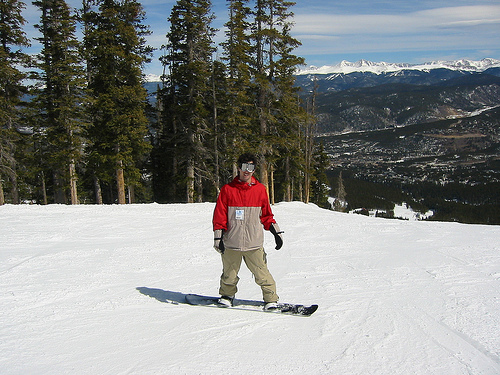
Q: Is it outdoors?
A: Yes, it is outdoors.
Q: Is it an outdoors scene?
A: Yes, it is outdoors.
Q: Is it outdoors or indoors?
A: It is outdoors.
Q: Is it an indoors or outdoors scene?
A: It is outdoors.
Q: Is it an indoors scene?
A: No, it is outdoors.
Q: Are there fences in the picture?
A: No, there are no fences.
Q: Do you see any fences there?
A: No, there are no fences.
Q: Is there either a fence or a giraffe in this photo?
A: No, there are no fences or giraffes.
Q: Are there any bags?
A: No, there are no bags.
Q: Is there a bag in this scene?
A: No, there are no bags.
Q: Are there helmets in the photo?
A: No, there are no helmets.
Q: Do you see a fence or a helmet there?
A: No, there are no helmets or fences.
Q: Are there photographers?
A: No, there are no photographers.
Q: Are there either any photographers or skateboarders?
A: No, there are no photographers or skateboarders.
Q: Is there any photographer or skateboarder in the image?
A: No, there are no photographers or skateboarders.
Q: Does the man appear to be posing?
A: Yes, the man is posing.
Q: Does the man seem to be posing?
A: Yes, the man is posing.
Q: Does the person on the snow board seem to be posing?
A: Yes, the man is posing.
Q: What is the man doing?
A: The man is posing.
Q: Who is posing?
A: The man is posing.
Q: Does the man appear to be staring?
A: No, the man is posing.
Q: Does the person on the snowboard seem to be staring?
A: No, the man is posing.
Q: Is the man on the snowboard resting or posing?
A: The man is posing.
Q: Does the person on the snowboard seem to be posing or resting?
A: The man is posing.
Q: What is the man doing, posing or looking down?
A: The man is posing.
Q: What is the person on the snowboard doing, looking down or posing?
A: The man is posing.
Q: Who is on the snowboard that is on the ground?
A: The man is on the snowboard.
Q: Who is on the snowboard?
A: The man is on the snowboard.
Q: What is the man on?
A: The man is on the snowboard.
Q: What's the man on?
A: The man is on the snowboard.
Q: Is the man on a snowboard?
A: Yes, the man is on a snowboard.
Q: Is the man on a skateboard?
A: No, the man is on a snowboard.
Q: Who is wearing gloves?
A: The man is wearing gloves.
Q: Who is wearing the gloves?
A: The man is wearing gloves.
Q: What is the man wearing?
A: The man is wearing gloves.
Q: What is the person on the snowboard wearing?
A: The man is wearing gloves.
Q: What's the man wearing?
A: The man is wearing gloves.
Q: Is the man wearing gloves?
A: Yes, the man is wearing gloves.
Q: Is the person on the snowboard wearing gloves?
A: Yes, the man is wearing gloves.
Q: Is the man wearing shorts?
A: No, the man is wearing gloves.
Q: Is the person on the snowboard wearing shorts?
A: No, the man is wearing gloves.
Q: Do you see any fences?
A: No, there are no fences.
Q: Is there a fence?
A: No, there are no fences.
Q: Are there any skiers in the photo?
A: No, there are no skiers.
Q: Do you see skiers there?
A: No, there are no skiers.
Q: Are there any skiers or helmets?
A: No, there are no skiers or helmets.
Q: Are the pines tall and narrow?
A: Yes, the pines are tall and narrow.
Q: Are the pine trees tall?
A: Yes, the pine trees are tall.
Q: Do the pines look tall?
A: Yes, the pines are tall.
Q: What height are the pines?
A: The pines are tall.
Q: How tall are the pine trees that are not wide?
A: The pine trees are tall.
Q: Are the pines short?
A: No, the pines are tall.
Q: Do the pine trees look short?
A: No, the pine trees are tall.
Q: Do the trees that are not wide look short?
A: No, the pine trees are tall.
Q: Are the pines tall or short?
A: The pines are tall.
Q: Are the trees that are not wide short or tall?
A: The pines are tall.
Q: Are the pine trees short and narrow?
A: No, the pine trees are narrow but tall.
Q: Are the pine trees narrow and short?
A: No, the pine trees are narrow but tall.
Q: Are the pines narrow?
A: Yes, the pines are narrow.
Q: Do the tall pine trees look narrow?
A: Yes, the pine trees are narrow.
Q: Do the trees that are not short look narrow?
A: Yes, the pine trees are narrow.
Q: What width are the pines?
A: The pines are narrow.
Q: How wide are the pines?
A: The pines are narrow.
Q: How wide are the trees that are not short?
A: The pines are narrow.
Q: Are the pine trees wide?
A: No, the pine trees are narrow.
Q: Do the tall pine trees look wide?
A: No, the pine trees are narrow.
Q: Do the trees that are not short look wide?
A: No, the pine trees are narrow.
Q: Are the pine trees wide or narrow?
A: The pine trees are narrow.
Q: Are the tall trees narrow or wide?
A: The pine trees are narrow.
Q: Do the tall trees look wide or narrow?
A: The pine trees are narrow.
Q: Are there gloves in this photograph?
A: Yes, there are gloves.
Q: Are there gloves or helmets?
A: Yes, there are gloves.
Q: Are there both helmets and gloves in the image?
A: No, there are gloves but no helmets.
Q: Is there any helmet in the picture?
A: No, there are no helmets.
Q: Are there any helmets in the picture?
A: No, there are no helmets.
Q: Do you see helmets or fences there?
A: No, there are no helmets or fences.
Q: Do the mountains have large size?
A: Yes, the mountains are large.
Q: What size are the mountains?
A: The mountains are large.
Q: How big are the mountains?
A: The mountains are large.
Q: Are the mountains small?
A: No, the mountains are large.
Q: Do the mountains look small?
A: No, the mountains are large.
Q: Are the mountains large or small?
A: The mountains are large.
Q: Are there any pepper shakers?
A: No, there are no pepper shakers.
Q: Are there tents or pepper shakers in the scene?
A: No, there are no pepper shakers or tents.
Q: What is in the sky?
A: The clouds are in the sky.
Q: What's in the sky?
A: The clouds are in the sky.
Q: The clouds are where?
A: The clouds are in the sky.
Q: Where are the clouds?
A: The clouds are in the sky.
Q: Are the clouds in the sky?
A: Yes, the clouds are in the sky.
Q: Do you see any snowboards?
A: Yes, there is a snowboard.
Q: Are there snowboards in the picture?
A: Yes, there is a snowboard.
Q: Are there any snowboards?
A: Yes, there is a snowboard.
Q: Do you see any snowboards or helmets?
A: Yes, there is a snowboard.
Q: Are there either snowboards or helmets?
A: Yes, there is a snowboard.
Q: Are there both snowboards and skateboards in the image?
A: No, there is a snowboard but no skateboards.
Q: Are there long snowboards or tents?
A: Yes, there is a long snowboard.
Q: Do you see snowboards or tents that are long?
A: Yes, the snowboard is long.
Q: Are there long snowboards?
A: Yes, there is a long snowboard.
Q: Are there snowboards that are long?
A: Yes, there is a snowboard that is long.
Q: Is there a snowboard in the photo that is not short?
A: Yes, there is a long snowboard.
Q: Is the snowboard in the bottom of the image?
A: Yes, the snowboard is in the bottom of the image.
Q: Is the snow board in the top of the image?
A: No, the snow board is in the bottom of the image.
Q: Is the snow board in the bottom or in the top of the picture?
A: The snow board is in the bottom of the image.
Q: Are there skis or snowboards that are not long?
A: No, there is a snowboard but it is long.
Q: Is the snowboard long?
A: Yes, the snowboard is long.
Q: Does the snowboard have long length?
A: Yes, the snowboard is long.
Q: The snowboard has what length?
A: The snowboard is long.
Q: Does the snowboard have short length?
A: No, the snowboard is long.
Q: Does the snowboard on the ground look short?
A: No, the snowboard is long.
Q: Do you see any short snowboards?
A: No, there is a snowboard but it is long.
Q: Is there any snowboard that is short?
A: No, there is a snowboard but it is long.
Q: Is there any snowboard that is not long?
A: No, there is a snowboard but it is long.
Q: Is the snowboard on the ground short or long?
A: The snowboard is long.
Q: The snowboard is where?
A: The snowboard is on the ground.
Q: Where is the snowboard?
A: The snowboard is on the ground.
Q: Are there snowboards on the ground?
A: Yes, there is a snowboard on the ground.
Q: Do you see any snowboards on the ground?
A: Yes, there is a snowboard on the ground.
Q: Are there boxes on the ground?
A: No, there is a snowboard on the ground.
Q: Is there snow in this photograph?
A: Yes, there is snow.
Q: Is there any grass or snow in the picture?
A: Yes, there is snow.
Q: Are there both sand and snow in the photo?
A: No, there is snow but no sand.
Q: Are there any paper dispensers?
A: No, there are no paper dispensers.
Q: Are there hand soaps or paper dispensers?
A: No, there are no paper dispensers or hand soaps.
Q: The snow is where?
A: The snow is on the ground.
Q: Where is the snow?
A: The snow is on the ground.